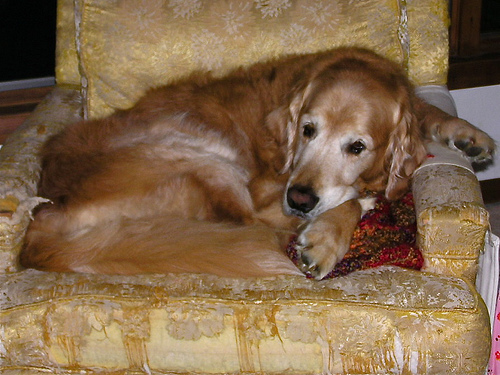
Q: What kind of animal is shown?
A: Dog.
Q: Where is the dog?
A: Chair.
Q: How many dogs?
A: One.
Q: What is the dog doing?
A: Laying down.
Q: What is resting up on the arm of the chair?
A: Dog's paw.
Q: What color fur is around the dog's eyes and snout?
A: White.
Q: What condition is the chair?
A: Old.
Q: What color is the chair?
A: Gold.